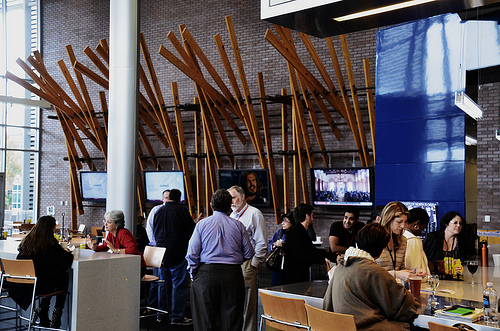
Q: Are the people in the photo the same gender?
A: No, they are both male and female.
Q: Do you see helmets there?
A: No, there are no helmets.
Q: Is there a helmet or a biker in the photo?
A: No, there are no helmets or bikers.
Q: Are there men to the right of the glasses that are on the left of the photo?
A: Yes, there is a man to the right of the glasses.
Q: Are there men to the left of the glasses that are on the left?
A: No, the man is to the right of the glasses.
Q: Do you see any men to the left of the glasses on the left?
A: No, the man is to the right of the glasses.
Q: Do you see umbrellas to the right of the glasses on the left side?
A: No, there is a man to the right of the glasses.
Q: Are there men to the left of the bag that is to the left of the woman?
A: Yes, there is a man to the left of the bag.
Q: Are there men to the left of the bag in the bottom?
A: Yes, there is a man to the left of the bag.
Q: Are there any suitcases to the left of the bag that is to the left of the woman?
A: No, there is a man to the left of the bag.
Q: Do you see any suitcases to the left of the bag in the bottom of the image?
A: No, there is a man to the left of the bag.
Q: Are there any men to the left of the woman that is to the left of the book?
A: Yes, there is a man to the left of the woman.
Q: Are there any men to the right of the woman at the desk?
A: No, the man is to the left of the woman.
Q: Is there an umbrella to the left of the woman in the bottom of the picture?
A: No, there is a man to the left of the woman.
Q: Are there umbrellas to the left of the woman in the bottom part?
A: No, there is a man to the left of the woman.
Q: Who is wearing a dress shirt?
A: The man is wearing a dress shirt.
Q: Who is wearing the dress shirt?
A: The man is wearing a dress shirt.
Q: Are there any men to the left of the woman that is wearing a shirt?
A: No, the man is to the right of the woman.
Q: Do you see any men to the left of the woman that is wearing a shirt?
A: No, the man is to the right of the woman.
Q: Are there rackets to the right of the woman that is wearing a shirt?
A: No, there is a man to the right of the woman.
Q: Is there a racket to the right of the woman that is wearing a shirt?
A: No, there is a man to the right of the woman.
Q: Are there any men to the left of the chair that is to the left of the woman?
A: Yes, there is a man to the left of the chair.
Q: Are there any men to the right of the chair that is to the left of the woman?
A: No, the man is to the left of the chair.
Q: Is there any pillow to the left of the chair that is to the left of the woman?
A: No, there is a man to the left of the chair.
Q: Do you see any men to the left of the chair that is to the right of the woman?
A: No, the man is to the right of the chair.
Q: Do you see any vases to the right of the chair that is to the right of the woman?
A: No, there is a man to the right of the chair.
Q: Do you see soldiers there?
A: No, there are no soldiers.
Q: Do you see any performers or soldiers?
A: No, there are no soldiers or performers.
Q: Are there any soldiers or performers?
A: No, there are no soldiers or performers.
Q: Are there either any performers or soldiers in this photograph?
A: No, there are no soldiers or performers.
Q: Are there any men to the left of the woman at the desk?
A: Yes, there is a man to the left of the woman.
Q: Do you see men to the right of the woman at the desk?
A: No, the man is to the left of the woman.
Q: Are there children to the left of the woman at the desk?
A: No, there is a man to the left of the woman.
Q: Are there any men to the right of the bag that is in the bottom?
A: Yes, there is a man to the right of the bag.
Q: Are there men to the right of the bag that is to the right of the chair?
A: Yes, there is a man to the right of the bag.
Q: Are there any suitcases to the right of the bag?
A: No, there is a man to the right of the bag.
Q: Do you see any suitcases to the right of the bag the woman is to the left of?
A: No, there is a man to the right of the bag.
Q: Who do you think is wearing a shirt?
A: The man is wearing a shirt.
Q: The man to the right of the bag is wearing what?
A: The man is wearing a shirt.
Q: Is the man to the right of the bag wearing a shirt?
A: Yes, the man is wearing a shirt.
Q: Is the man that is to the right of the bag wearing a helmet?
A: No, the man is wearing a shirt.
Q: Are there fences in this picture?
A: No, there are no fences.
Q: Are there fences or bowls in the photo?
A: No, there are no fences or bowls.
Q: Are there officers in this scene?
A: No, there are no officers.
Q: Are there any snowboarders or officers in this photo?
A: No, there are no officers or snowboarders.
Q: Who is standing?
A: The man is standing.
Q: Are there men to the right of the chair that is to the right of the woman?
A: Yes, there is a man to the right of the chair.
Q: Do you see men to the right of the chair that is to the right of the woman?
A: Yes, there is a man to the right of the chair.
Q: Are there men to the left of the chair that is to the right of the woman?
A: No, the man is to the right of the chair.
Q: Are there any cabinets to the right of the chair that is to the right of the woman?
A: No, there is a man to the right of the chair.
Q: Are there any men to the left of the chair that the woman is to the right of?
A: Yes, there is a man to the left of the chair.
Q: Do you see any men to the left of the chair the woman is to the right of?
A: Yes, there is a man to the left of the chair.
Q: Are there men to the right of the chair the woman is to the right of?
A: No, the man is to the left of the chair.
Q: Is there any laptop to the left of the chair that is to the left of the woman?
A: No, there is a man to the left of the chair.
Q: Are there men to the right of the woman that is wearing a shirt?
A: Yes, there is a man to the right of the woman.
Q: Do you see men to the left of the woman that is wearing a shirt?
A: No, the man is to the right of the woman.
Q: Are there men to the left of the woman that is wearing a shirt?
A: No, the man is to the right of the woman.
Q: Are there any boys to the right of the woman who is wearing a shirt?
A: No, there is a man to the right of the woman.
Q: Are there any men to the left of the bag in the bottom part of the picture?
A: Yes, there is a man to the left of the bag.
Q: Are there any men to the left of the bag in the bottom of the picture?
A: Yes, there is a man to the left of the bag.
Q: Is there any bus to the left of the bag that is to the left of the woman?
A: No, there is a man to the left of the bag.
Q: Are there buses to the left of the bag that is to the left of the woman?
A: No, there is a man to the left of the bag.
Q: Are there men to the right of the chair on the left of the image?
A: Yes, there is a man to the right of the chair.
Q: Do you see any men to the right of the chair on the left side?
A: Yes, there is a man to the right of the chair.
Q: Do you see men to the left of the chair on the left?
A: No, the man is to the right of the chair.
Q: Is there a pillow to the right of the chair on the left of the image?
A: No, there is a man to the right of the chair.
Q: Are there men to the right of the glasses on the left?
A: Yes, there is a man to the right of the glasses.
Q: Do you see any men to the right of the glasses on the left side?
A: Yes, there is a man to the right of the glasses.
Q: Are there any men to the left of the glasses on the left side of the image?
A: No, the man is to the right of the glasses.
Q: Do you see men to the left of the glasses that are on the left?
A: No, the man is to the right of the glasses.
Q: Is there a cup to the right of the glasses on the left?
A: No, there is a man to the right of the glasses.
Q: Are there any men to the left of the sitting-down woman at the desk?
A: Yes, there is a man to the left of the woman.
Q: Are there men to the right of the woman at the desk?
A: No, the man is to the left of the woman.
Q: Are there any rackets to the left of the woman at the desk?
A: No, there is a man to the left of the woman.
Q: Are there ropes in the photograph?
A: No, there are no ropes.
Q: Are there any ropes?
A: No, there are no ropes.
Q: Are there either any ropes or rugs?
A: No, there are no ropes or rugs.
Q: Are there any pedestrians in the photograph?
A: No, there are no pedestrians.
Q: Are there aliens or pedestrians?
A: No, there are no pedestrians or aliens.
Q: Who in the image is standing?
A: The man is standing.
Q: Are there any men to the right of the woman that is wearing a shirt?
A: Yes, there is a man to the right of the woman.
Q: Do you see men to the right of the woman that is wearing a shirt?
A: Yes, there is a man to the right of the woman.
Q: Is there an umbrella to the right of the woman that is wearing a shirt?
A: No, there is a man to the right of the woman.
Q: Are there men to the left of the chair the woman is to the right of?
A: Yes, there is a man to the left of the chair.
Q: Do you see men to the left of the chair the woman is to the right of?
A: Yes, there is a man to the left of the chair.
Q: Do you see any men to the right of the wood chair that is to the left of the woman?
A: No, the man is to the left of the chair.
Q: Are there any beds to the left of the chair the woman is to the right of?
A: No, there is a man to the left of the chair.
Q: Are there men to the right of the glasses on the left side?
A: Yes, there is a man to the right of the glasses.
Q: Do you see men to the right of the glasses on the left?
A: Yes, there is a man to the right of the glasses.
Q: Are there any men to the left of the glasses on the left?
A: No, the man is to the right of the glasses.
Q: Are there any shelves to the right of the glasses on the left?
A: No, there is a man to the right of the glasses.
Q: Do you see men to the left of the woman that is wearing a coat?
A: Yes, there is a man to the left of the woman.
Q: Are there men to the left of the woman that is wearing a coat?
A: Yes, there is a man to the left of the woman.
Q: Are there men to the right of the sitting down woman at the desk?
A: No, the man is to the left of the woman.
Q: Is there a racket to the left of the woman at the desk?
A: No, there is a man to the left of the woman.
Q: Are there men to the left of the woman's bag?
A: Yes, there is a man to the left of the bag.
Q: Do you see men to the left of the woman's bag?
A: Yes, there is a man to the left of the bag.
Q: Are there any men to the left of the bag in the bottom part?
A: Yes, there is a man to the left of the bag.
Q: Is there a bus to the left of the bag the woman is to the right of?
A: No, there is a man to the left of the bag.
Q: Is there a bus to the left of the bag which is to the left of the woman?
A: No, there is a man to the left of the bag.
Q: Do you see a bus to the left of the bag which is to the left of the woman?
A: No, there is a man to the left of the bag.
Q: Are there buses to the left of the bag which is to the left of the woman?
A: No, there is a man to the left of the bag.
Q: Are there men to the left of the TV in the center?
A: Yes, there is a man to the left of the television.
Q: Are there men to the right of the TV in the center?
A: No, the man is to the left of the TV.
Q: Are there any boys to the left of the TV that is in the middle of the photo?
A: No, there is a man to the left of the TV.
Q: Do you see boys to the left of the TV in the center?
A: No, there is a man to the left of the TV.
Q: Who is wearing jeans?
A: The man is wearing jeans.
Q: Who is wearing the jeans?
A: The man is wearing jeans.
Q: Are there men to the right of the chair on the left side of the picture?
A: Yes, there is a man to the right of the chair.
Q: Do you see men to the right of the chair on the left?
A: Yes, there is a man to the right of the chair.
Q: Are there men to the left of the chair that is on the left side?
A: No, the man is to the right of the chair.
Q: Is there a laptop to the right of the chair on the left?
A: No, there is a man to the right of the chair.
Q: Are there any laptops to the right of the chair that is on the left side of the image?
A: No, there is a man to the right of the chair.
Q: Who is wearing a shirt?
A: The man is wearing a shirt.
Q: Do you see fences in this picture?
A: No, there are no fences.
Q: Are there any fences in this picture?
A: No, there are no fences.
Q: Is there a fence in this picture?
A: No, there are no fences.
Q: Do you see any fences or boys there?
A: No, there are no fences or boys.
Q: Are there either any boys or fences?
A: No, there are no fences or boys.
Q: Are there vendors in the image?
A: No, there are no vendors.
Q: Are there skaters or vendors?
A: No, there are no vendors or skaters.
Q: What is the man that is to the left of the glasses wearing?
A: The man is wearing a shirt.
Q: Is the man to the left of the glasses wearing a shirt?
A: Yes, the man is wearing a shirt.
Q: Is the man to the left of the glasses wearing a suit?
A: No, the man is wearing a shirt.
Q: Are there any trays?
A: No, there are no trays.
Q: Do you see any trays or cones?
A: No, there are no trays or cones.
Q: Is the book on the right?
A: Yes, the book is on the right of the image.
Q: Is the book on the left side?
A: No, the book is on the right of the image.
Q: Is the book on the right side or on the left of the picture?
A: The book is on the right of the image.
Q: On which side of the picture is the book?
A: The book is on the right of the image.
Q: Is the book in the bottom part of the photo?
A: Yes, the book is in the bottom of the image.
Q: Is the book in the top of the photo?
A: No, the book is in the bottom of the image.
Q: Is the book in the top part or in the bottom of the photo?
A: The book is in the bottom of the image.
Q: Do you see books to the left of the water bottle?
A: Yes, there is a book to the left of the water bottle.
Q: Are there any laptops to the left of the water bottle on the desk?
A: No, there is a book to the left of the water bottle.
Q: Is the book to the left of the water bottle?
A: Yes, the book is to the left of the water bottle.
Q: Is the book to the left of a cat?
A: No, the book is to the left of the water bottle.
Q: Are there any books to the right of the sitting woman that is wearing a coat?
A: Yes, there is a book to the right of the woman.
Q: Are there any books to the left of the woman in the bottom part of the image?
A: No, the book is to the right of the woman.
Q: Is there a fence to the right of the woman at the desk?
A: No, there is a book to the right of the woman.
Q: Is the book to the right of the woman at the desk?
A: Yes, the book is to the right of the woman.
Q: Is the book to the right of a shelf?
A: No, the book is to the right of the woman.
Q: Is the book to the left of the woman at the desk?
A: No, the book is to the right of the woman.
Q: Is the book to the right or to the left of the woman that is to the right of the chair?
A: The book is to the right of the woman.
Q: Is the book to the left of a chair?
A: No, the book is to the right of a chair.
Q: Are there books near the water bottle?
A: Yes, there is a book near the water bottle.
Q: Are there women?
A: Yes, there is a woman.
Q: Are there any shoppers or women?
A: Yes, there is a woman.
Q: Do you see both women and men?
A: Yes, there are both a woman and a man.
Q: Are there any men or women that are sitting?
A: Yes, the woman is sitting.